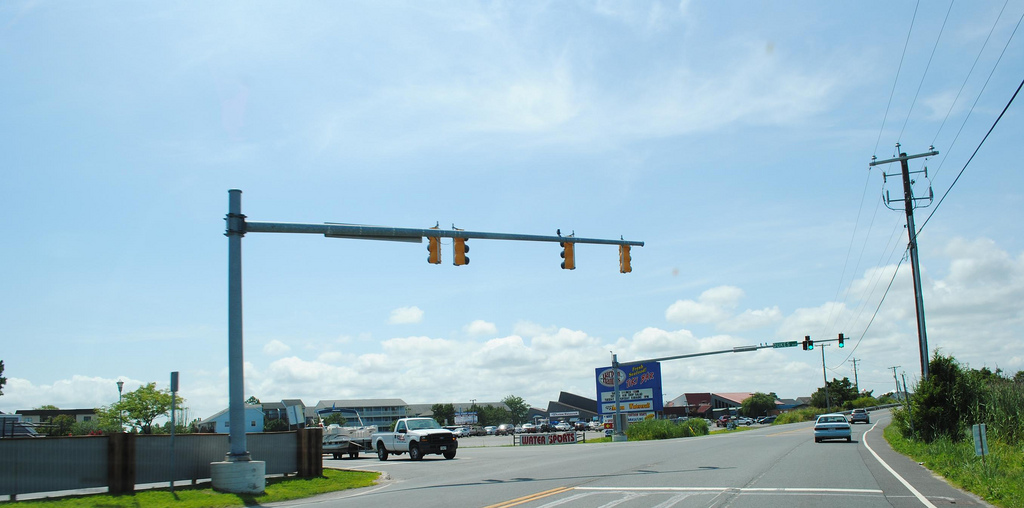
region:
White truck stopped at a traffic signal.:
[362, 402, 458, 463]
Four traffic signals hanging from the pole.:
[409, 212, 654, 288]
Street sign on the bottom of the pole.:
[315, 215, 434, 241]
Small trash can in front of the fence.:
[102, 414, 145, 498]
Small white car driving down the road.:
[792, 397, 873, 446]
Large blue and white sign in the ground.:
[582, 356, 669, 440]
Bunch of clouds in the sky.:
[301, 300, 997, 367]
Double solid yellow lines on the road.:
[506, 487, 596, 504]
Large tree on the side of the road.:
[906, 350, 990, 452]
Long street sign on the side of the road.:
[157, 361, 174, 460]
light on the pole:
[607, 241, 647, 280]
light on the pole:
[554, 237, 581, 277]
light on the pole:
[422, 215, 446, 274]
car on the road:
[820, 413, 855, 443]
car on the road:
[485, 421, 508, 429]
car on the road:
[495, 421, 522, 437]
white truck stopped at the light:
[374, 416, 460, 464]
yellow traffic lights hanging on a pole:
[420, 222, 648, 284]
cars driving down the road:
[807, 399, 872, 442]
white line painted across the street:
[571, 480, 878, 503]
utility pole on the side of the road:
[855, 121, 983, 461]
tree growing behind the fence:
[106, 380, 176, 428]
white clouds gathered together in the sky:
[322, 304, 570, 378]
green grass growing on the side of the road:
[284, 470, 338, 497]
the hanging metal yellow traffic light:
[427, 232, 443, 268]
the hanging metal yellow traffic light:
[450, 230, 474, 268]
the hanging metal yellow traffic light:
[557, 237, 578, 273]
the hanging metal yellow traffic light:
[617, 241, 633, 280]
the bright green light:
[806, 345, 820, 350]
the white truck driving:
[368, 404, 460, 462]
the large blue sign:
[596, 352, 658, 423]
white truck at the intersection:
[372, 413, 459, 462]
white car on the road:
[812, 413, 852, 442]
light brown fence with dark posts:
[5, 426, 325, 496]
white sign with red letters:
[517, 430, 579, 443]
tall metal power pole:
[869, 149, 940, 388]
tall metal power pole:
[852, 357, 860, 402]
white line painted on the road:
[572, 484, 885, 491]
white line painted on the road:
[860, 411, 936, 504]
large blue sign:
[591, 361, 659, 423]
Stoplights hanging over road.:
[250, 219, 650, 276]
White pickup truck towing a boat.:
[318, 412, 462, 460]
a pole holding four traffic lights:
[206, 174, 660, 486]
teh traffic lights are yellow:
[413, 219, 647, 283]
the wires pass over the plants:
[829, 16, 1022, 452]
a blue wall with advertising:
[587, 348, 670, 433]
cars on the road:
[797, 388, 892, 452]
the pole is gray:
[205, 174, 277, 501]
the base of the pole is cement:
[199, 428, 271, 506]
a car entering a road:
[304, 383, 575, 501]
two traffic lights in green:
[794, 324, 852, 359]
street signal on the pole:
[418, 225, 442, 267]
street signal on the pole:
[450, 228, 464, 271]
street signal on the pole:
[555, 231, 575, 271]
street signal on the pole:
[612, 237, 633, 269]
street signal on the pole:
[798, 334, 812, 351]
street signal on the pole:
[832, 323, 849, 352]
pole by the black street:
[222, 182, 251, 454]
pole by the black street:
[602, 343, 622, 442]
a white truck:
[369, 413, 459, 467]